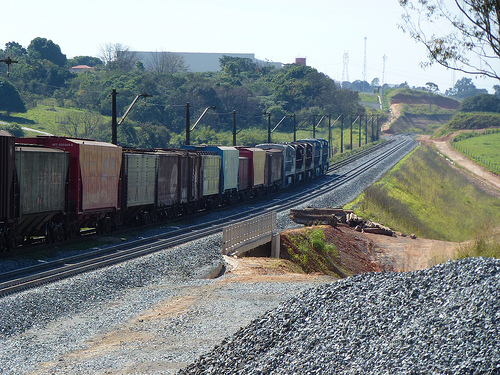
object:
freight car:
[0, 134, 335, 252]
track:
[0, 128, 412, 299]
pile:
[180, 254, 499, 375]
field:
[455, 132, 500, 173]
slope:
[344, 143, 498, 258]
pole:
[111, 88, 118, 144]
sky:
[2, 1, 499, 94]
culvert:
[243, 239, 294, 261]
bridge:
[222, 211, 283, 259]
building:
[71, 64, 93, 76]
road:
[432, 141, 498, 190]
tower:
[361, 35, 367, 87]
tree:
[398, 1, 499, 80]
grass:
[285, 227, 336, 264]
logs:
[286, 209, 348, 225]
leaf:
[415, 34, 420, 39]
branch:
[455, 1, 485, 33]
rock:
[269, 313, 272, 318]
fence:
[436, 146, 458, 168]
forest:
[0, 35, 357, 144]